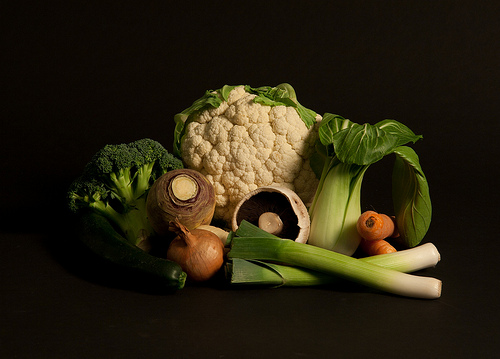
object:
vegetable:
[166, 215, 233, 279]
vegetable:
[355, 210, 400, 239]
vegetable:
[150, 165, 219, 230]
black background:
[0, 2, 499, 356]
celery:
[223, 218, 442, 300]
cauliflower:
[171, 82, 327, 232]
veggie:
[308, 112, 432, 257]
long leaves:
[307, 112, 431, 257]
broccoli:
[64, 138, 187, 246]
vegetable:
[67, 61, 452, 309]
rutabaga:
[145, 168, 217, 243]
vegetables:
[67, 82, 445, 300]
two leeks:
[226, 218, 443, 299]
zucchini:
[83, 207, 188, 290]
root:
[171, 174, 199, 202]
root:
[365, 215, 377, 228]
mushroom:
[230, 185, 311, 246]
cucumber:
[81, 204, 187, 290]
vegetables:
[221, 219, 443, 299]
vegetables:
[223, 243, 440, 287]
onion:
[171, 217, 226, 279]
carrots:
[356, 210, 401, 255]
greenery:
[69, 82, 442, 300]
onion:
[164, 216, 226, 282]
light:
[206, 244, 220, 259]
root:
[188, 186, 321, 285]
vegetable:
[62, 140, 186, 252]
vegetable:
[144, 167, 221, 229]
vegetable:
[166, 214, 221, 282]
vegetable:
[168, 80, 337, 227]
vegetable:
[298, 107, 430, 268]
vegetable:
[354, 207, 400, 258]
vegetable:
[232, 187, 310, 245]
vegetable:
[225, 220, 443, 298]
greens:
[305, 112, 433, 256]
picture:
[48, 43, 468, 328]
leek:
[224, 217, 442, 299]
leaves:
[314, 112, 423, 166]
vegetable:
[252, 81, 433, 260]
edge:
[227, 271, 331, 288]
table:
[3, 159, 499, 358]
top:
[75, 138, 185, 181]